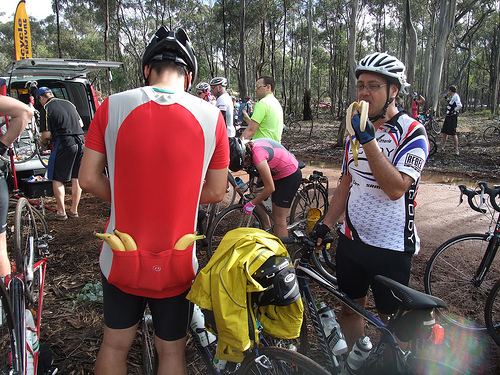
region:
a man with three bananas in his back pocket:
[29, 14, 276, 349]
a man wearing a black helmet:
[44, 10, 231, 180]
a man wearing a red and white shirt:
[65, 7, 244, 327]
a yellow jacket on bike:
[168, 200, 348, 369]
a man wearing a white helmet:
[314, 25, 449, 168]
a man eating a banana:
[315, 32, 444, 188]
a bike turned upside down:
[7, 191, 89, 366]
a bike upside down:
[4, 182, 92, 373]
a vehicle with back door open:
[8, 42, 140, 197]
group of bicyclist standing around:
[19, 16, 477, 352]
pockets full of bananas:
[80, 206, 220, 306]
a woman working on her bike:
[220, 120, 315, 227]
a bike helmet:
[345, 30, 420, 90]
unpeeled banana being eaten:
[325, 90, 395, 170]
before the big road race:
[75, 55, 420, 365]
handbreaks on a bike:
[445, 170, 495, 220]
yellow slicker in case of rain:
[165, 200, 315, 365]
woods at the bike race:
[280, 55, 340, 160]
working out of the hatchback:
[0, 55, 125, 215]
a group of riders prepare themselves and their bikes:
[5, 60, 440, 367]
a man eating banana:
[307, 30, 418, 155]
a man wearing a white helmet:
[321, 43, 419, 126]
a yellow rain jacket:
[208, 224, 323, 374]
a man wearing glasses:
[231, 65, 293, 107]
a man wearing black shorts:
[426, 72, 468, 167]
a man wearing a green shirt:
[238, 72, 290, 157]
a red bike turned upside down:
[0, 170, 69, 373]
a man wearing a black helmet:
[129, 8, 199, 88]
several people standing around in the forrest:
[1, 32, 336, 323]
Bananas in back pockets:
[53, 186, 230, 368]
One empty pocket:
[94, 208, 214, 297]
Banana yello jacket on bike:
[150, 171, 323, 363]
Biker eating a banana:
[316, 40, 444, 272]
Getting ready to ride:
[78, 19, 476, 351]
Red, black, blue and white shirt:
[296, 91, 450, 276]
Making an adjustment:
[227, 128, 324, 245]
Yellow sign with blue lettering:
[5, 0, 53, 68]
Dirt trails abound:
[23, 152, 499, 358]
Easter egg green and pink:
[214, 64, 323, 214]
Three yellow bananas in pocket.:
[93, 215, 207, 266]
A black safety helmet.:
[138, 17, 202, 87]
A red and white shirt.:
[88, 85, 231, 297]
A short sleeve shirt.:
[83, 78, 239, 291]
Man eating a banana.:
[328, 49, 438, 299]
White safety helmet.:
[350, 42, 415, 114]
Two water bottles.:
[313, 294, 382, 373]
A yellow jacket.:
[188, 219, 316, 360]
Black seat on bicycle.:
[368, 266, 446, 321]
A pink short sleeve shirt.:
[241, 135, 303, 195]